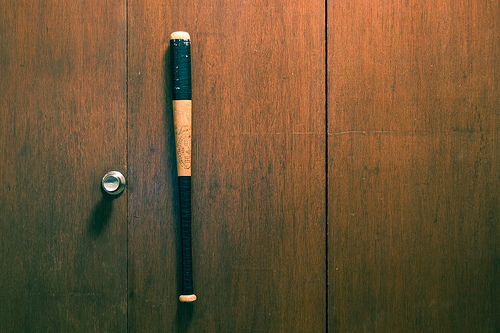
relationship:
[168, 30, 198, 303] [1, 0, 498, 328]
baseball on table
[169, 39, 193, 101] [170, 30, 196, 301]
tape on bat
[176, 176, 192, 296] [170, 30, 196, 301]
grip tape on bottom of bat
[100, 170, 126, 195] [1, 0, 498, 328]
object on table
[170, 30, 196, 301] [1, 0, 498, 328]
bat on table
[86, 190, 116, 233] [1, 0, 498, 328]
shadow on table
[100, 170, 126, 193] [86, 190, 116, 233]
object casting shadow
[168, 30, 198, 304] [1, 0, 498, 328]
baseball lying on table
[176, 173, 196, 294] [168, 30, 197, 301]
tape wrapped around bat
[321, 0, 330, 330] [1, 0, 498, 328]
seam between wood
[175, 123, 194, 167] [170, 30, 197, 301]
stamp in wood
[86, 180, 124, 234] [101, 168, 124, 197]
shadow cast by door knob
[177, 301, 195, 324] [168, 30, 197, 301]
shadow cast by bat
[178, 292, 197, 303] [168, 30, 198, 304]
knob of baseball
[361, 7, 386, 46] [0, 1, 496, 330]
specks on door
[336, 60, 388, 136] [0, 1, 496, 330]
specks on door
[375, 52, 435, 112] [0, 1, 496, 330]
specks on door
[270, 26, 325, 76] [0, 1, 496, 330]
specks on door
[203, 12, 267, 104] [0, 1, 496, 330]
specks on door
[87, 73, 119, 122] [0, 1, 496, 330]
specks on door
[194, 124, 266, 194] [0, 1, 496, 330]
specks on door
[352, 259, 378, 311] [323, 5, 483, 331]
strike on door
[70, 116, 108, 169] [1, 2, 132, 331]
strike on door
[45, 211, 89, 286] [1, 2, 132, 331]
strike on door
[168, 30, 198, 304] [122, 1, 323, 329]
baseball on door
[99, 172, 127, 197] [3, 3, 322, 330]
door knob on door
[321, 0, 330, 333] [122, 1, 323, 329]
seam between door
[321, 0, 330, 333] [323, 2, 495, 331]
seam between door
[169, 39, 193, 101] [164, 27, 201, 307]
tape across bat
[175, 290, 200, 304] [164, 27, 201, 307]
knob of bat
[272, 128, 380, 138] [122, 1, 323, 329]
scuff across door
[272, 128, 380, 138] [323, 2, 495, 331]
scuff across door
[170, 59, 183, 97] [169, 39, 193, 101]
specs along tape